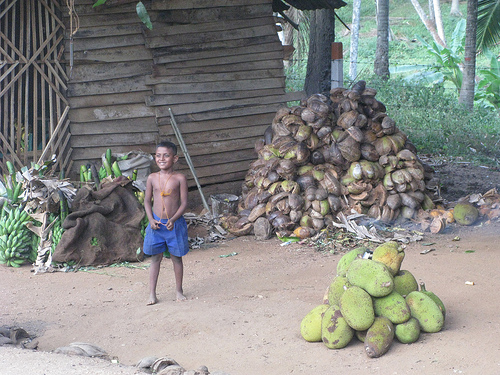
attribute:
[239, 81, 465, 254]
melons — rotten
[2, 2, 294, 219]
store — at back, wooden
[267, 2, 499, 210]
fence — barbed, wire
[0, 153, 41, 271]
bananas — at back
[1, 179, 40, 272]
bananas — green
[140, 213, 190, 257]
short — blue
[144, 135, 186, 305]
boy — barefooted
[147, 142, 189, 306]
boy — half naked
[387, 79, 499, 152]
plants — green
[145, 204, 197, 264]
shorts — blue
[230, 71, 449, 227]
fuits — destroyed